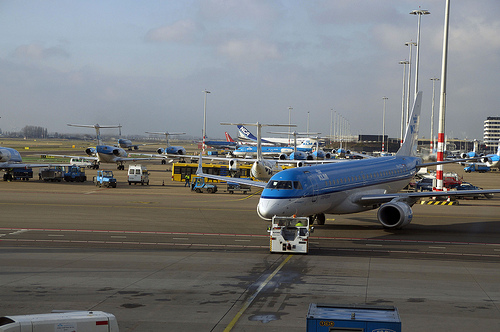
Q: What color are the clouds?
A: Gray.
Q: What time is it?
A: Afternoon.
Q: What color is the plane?
A: Blue.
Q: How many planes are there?
A: More than three.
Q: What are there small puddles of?
A: Water.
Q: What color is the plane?
A: Blue and white.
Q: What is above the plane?
A: The sky.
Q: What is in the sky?
A: Clouds.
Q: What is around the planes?
A: Cars.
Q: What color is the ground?
A: Gray.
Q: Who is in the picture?
A: No one.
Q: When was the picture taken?
A: Daytime.